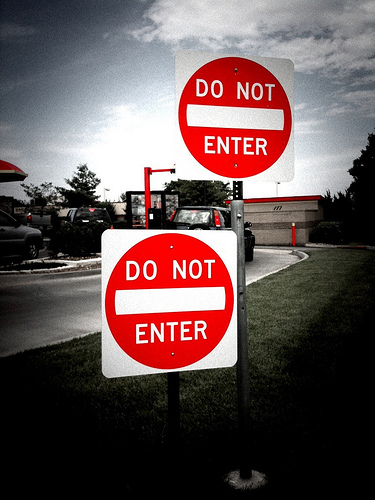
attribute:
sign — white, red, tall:
[174, 48, 294, 184]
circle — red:
[104, 232, 234, 369]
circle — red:
[179, 56, 290, 179]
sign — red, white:
[98, 228, 239, 373]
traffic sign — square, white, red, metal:
[107, 226, 242, 393]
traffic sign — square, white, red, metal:
[94, 223, 247, 394]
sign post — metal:
[164, 336, 181, 498]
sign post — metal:
[231, 197, 248, 479]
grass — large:
[276, 254, 368, 356]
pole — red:
[287, 222, 300, 254]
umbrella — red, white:
[0, 164, 28, 187]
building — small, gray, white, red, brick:
[248, 187, 305, 238]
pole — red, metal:
[137, 155, 173, 210]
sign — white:
[188, 50, 303, 193]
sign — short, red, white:
[99, 229, 238, 498]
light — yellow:
[125, 132, 190, 363]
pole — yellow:
[134, 166, 171, 340]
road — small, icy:
[27, 260, 115, 339]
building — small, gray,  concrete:
[253, 191, 328, 235]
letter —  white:
[189, 76, 208, 100]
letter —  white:
[123, 259, 139, 287]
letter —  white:
[141, 260, 157, 281]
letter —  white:
[173, 258, 185, 279]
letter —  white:
[188, 260, 202, 283]